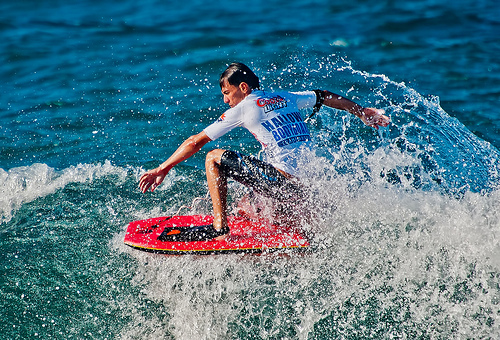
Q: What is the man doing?
A: Riding his boogie board.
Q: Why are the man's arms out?
A: For balance.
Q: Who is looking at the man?
A: The photographer.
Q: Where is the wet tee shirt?
A: On the man's back.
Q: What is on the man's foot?
A: A black flipper.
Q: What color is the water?
A: Blue.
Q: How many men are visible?
A: One.